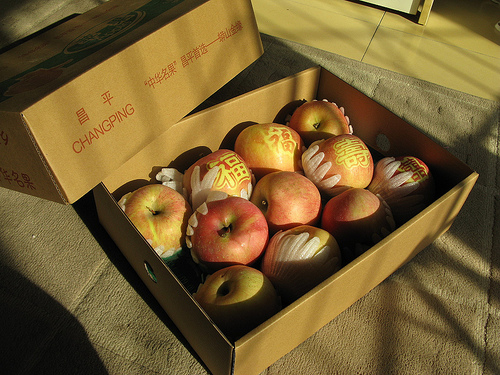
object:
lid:
[0, 1, 265, 205]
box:
[93, 64, 479, 375]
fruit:
[253, 171, 320, 226]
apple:
[192, 196, 268, 268]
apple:
[198, 265, 275, 322]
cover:
[263, 233, 338, 295]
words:
[72, 107, 90, 125]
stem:
[221, 225, 232, 239]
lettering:
[208, 151, 252, 188]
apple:
[182, 149, 253, 200]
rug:
[1, 1, 500, 375]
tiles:
[343, 20, 500, 79]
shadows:
[2, 256, 110, 375]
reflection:
[405, 25, 433, 58]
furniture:
[343, 0, 435, 27]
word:
[73, 141, 83, 153]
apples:
[310, 134, 376, 188]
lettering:
[267, 127, 296, 152]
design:
[0, 1, 178, 100]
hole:
[141, 259, 158, 284]